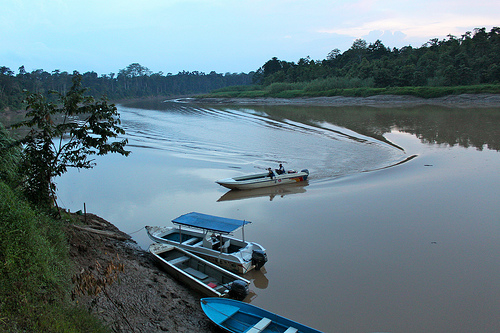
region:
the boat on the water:
[210, 160, 321, 197]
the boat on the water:
[142, 205, 291, 275]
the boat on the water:
[136, 240, 258, 300]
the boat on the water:
[188, 288, 328, 331]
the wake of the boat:
[305, 141, 442, 181]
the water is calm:
[320, 200, 466, 268]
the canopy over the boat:
[175, 215, 250, 228]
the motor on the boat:
[249, 246, 273, 270]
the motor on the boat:
[223, 277, 254, 297]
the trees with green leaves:
[276, 56, 494, 68]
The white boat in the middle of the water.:
[208, 165, 310, 186]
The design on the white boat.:
[290, 168, 310, 180]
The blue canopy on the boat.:
[170, 209, 250, 232]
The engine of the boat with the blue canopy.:
[250, 245, 269, 270]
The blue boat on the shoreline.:
[197, 296, 324, 331]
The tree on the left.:
[17, 70, 125, 235]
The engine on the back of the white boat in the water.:
[301, 164, 311, 181]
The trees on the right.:
[211, 24, 498, 97]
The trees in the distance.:
[18, 63, 263, 100]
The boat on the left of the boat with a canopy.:
[143, 240, 250, 302]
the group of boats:
[143, 162, 321, 330]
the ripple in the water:
[62, 97, 418, 182]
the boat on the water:
[266, 163, 285, 180]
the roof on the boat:
[171, 211, 249, 234]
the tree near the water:
[5, 71, 131, 220]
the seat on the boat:
[164, 254, 189, 264]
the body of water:
[17, 95, 497, 330]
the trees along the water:
[0, 25, 497, 330]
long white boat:
[211, 163, 311, 195]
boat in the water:
[200, 165, 309, 194]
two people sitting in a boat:
[261, 162, 289, 182]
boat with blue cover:
[140, 210, 275, 272]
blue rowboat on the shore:
[192, 290, 332, 331]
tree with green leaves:
[24, 68, 132, 205]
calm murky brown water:
[282, 194, 474, 289]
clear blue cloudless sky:
[14, 9, 276, 89]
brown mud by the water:
[73, 229, 200, 331]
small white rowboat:
[149, 238, 259, 297]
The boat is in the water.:
[213, 146, 334, 208]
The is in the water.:
[132, 206, 287, 277]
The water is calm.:
[16, 80, 499, 331]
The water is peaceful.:
[16, 68, 498, 332]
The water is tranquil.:
[20, 65, 499, 328]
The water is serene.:
[8, 65, 499, 329]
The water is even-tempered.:
[11, 55, 498, 329]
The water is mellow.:
[15, 72, 499, 332]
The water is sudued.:
[16, 68, 499, 331]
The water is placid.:
[15, 84, 499, 330]